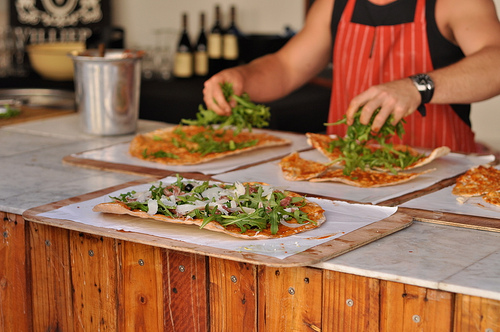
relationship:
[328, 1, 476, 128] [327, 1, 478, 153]
tank under apron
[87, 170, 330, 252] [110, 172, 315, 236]
tortilla with vegetable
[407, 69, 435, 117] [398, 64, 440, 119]
watch on wrist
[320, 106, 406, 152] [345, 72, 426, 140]
vegetables in hand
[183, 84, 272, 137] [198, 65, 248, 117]
vegetables in hand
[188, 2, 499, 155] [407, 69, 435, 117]
chef wearing watch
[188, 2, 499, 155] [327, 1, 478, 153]
chef wearing apron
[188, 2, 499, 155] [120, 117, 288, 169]
chef topping pizza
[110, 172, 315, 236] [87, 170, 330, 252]
vegetable on tortilla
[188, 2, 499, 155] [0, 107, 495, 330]
chef before counter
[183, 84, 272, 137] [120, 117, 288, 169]
vegetables on tortilla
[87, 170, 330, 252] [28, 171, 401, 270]
tortilla over paper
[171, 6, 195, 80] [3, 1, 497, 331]
bottle in kitchen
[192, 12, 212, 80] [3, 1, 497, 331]
bottle in kitchen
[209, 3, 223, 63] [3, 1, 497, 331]
bottle in kitchen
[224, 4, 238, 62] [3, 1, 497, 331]
bottle in kitchen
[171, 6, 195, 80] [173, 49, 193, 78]
bottle has label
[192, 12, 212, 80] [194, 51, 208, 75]
bottle has label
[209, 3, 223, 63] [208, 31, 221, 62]
bottle has label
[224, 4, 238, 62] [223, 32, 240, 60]
bottle has label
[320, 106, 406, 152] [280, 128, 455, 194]
vegetables on tortilla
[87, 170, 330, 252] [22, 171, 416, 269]
tortilla on board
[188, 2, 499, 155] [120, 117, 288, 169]
chef making pizza